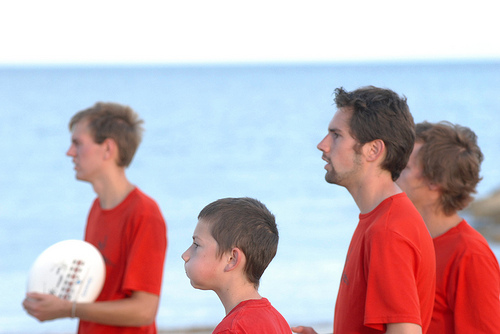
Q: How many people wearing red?
A: Four.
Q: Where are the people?
A: At the beach.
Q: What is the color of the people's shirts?
A: Red.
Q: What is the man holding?
A: Frisbee.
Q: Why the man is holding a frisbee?
A: To play with.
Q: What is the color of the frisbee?
A: White.